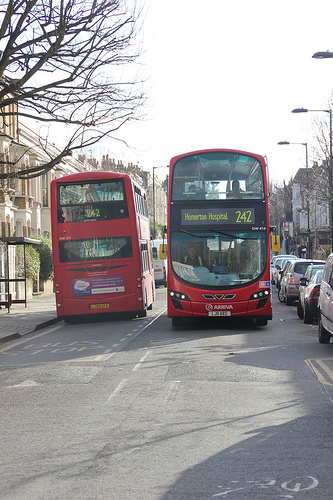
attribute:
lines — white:
[107, 347, 151, 407]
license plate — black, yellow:
[88, 303, 110, 309]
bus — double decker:
[151, 119, 286, 344]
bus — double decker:
[46, 170, 155, 324]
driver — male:
[174, 235, 212, 272]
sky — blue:
[130, 47, 223, 122]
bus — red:
[163, 147, 271, 332]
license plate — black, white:
[209, 309, 232, 316]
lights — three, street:
[270, 49, 332, 206]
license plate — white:
[203, 309, 230, 315]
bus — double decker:
[164, 149, 277, 325]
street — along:
[130, 344, 270, 454]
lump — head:
[167, 289, 191, 301]